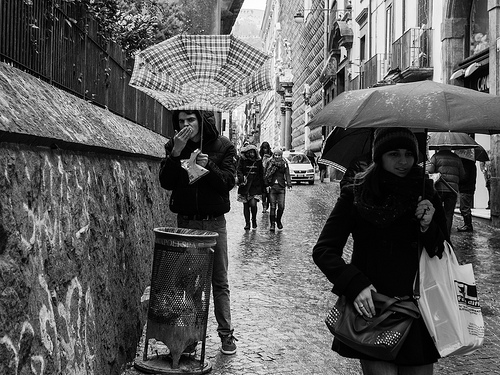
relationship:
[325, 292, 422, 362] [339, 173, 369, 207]
bag on shoulder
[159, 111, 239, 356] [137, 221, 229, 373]
man eating in front of waste bin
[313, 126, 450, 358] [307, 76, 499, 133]
person holding umbrella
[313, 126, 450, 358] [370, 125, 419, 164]
person wearing hat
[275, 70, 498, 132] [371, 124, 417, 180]
umbrella over head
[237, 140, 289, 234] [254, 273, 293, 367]
people walking down road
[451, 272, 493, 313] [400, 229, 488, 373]
image on bag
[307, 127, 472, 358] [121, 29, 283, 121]
person holding umbrella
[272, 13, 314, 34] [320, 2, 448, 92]
lamp anchored to wall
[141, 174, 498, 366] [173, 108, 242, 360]
road with pedestrians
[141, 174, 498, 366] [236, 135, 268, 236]
road with pedestrians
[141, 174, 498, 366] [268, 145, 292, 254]
road with pedestrians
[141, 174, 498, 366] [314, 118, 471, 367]
road with pedestrians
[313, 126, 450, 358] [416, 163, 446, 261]
person has arm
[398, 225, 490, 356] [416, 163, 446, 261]
bag carried in arm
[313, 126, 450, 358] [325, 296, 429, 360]
person holding bag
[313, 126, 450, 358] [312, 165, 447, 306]
person wearing shirt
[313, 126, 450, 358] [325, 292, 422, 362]
person holding bag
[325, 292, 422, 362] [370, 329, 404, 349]
bag with studs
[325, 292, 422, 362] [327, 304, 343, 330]
bag with studs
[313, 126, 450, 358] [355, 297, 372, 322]
person has finger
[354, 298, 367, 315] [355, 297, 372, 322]
ring on finger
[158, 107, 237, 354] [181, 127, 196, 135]
man has mouth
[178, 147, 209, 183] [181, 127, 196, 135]
food going into mouth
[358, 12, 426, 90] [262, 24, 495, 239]
balcony on building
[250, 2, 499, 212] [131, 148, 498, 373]
buildings on street